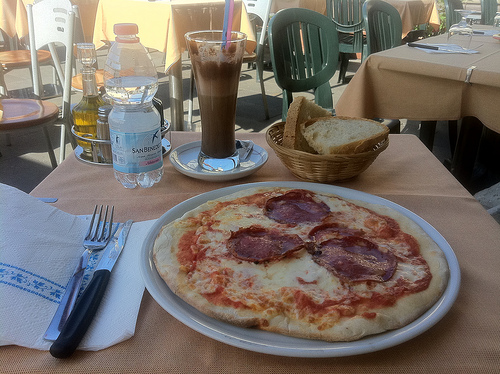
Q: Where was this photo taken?
A: At a restaurant.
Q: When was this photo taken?
A: Outside, during the day time.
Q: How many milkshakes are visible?
A: One.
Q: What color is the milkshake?
A: Brown.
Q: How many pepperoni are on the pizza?
A: Three.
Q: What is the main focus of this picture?
A: A plate of pizza.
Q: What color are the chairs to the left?
A: Green.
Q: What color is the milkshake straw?
A: Blue.